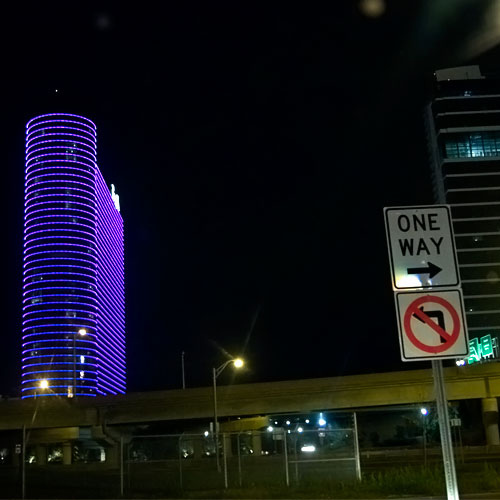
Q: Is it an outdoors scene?
A: Yes, it is outdoors.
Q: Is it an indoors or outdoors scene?
A: It is outdoors.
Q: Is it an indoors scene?
A: No, it is outdoors.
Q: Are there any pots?
A: No, there are no pots.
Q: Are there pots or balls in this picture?
A: No, there are no pots or balls.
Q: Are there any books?
A: No, there are no books.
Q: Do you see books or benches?
A: No, there are no books or benches.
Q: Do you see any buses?
A: No, there are no buses.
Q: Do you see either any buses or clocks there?
A: No, there are no buses or clocks.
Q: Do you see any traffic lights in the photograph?
A: No, there are no traffic lights.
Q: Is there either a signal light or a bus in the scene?
A: No, there are no traffic lights or buses.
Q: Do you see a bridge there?
A: Yes, there is a bridge.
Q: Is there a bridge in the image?
A: Yes, there is a bridge.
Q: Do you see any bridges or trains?
A: Yes, there is a bridge.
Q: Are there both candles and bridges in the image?
A: No, there is a bridge but no candles.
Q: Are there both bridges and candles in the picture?
A: No, there is a bridge but no candles.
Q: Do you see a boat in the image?
A: No, there are no boats.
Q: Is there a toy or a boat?
A: No, there are no boats or toys.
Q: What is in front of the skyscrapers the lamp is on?
A: The bridge is in front of the skyscrapers.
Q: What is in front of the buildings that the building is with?
A: The bridge is in front of the skyscrapers.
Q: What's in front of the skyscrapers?
A: The bridge is in front of the skyscrapers.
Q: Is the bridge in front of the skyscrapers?
A: Yes, the bridge is in front of the skyscrapers.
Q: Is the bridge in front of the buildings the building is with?
A: Yes, the bridge is in front of the skyscrapers.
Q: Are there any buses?
A: No, there are no buses.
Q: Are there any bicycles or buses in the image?
A: No, there are no buses or bicycles.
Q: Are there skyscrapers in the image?
A: Yes, there are skyscrapers.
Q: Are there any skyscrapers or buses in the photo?
A: Yes, there are skyscrapers.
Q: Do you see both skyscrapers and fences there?
A: Yes, there are both skyscrapers and a fence.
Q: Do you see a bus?
A: No, there are no buses.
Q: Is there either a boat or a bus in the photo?
A: No, there are no buses or boats.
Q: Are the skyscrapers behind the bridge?
A: Yes, the skyscrapers are behind the bridge.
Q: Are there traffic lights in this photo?
A: No, there are no traffic lights.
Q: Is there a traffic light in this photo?
A: No, there are no traffic lights.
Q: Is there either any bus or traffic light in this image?
A: No, there are no traffic lights or buses.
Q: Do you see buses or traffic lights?
A: No, there are no traffic lights or buses.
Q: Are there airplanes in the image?
A: No, there are no airplanes.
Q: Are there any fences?
A: Yes, there is a fence.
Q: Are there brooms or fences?
A: Yes, there is a fence.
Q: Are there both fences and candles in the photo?
A: No, there is a fence but no candles.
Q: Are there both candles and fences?
A: No, there is a fence but no candles.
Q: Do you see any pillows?
A: No, there are no pillows.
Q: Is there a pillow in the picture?
A: No, there are no pillows.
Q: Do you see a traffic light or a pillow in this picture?
A: No, there are no pillows or traffic lights.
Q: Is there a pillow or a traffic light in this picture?
A: No, there are no pillows or traffic lights.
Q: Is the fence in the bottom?
A: Yes, the fence is in the bottom of the image.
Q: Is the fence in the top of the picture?
A: No, the fence is in the bottom of the image.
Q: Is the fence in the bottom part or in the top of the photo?
A: The fence is in the bottom of the image.